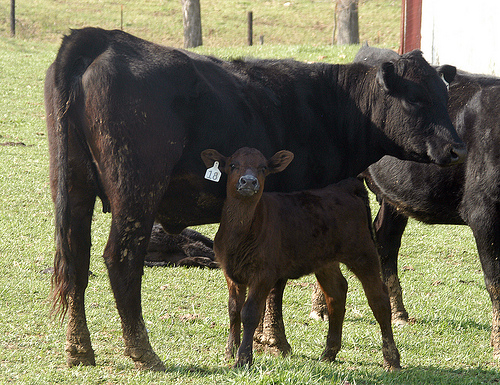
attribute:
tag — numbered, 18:
[202, 158, 226, 186]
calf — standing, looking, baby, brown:
[196, 142, 415, 371]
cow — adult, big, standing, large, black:
[46, 21, 470, 371]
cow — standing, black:
[342, 37, 500, 365]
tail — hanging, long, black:
[44, 21, 98, 327]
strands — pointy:
[44, 210, 80, 321]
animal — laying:
[145, 218, 221, 276]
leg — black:
[101, 170, 176, 372]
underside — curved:
[366, 148, 469, 239]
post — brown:
[245, 5, 259, 51]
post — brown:
[6, 0, 23, 41]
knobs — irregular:
[113, 209, 156, 270]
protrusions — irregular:
[125, 103, 174, 221]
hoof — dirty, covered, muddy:
[126, 349, 167, 373]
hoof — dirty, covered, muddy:
[64, 343, 97, 372]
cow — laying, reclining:
[146, 219, 230, 275]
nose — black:
[234, 167, 262, 201]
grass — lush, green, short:
[5, 0, 500, 379]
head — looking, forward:
[196, 144, 297, 209]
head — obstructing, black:
[371, 46, 466, 169]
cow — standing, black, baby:
[201, 131, 411, 373]